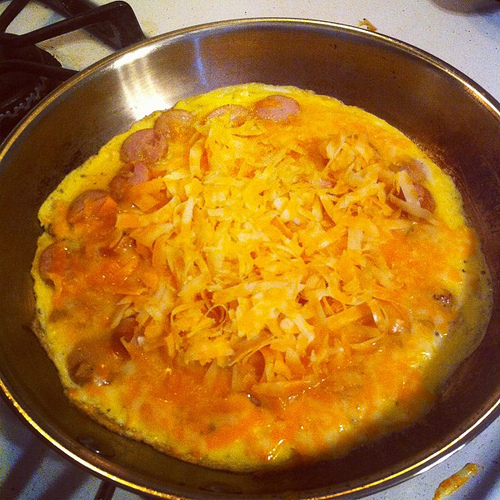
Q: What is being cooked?
A: An omelet.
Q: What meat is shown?
A: Sausage.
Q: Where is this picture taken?
A: A kitchen.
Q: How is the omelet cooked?
A: On the stove.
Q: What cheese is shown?
A: Cheddar.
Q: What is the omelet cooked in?
A: A pan.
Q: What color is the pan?
A: Silver.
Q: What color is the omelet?
A: Yellow.